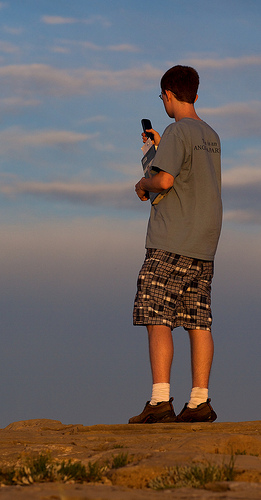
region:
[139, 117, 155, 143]
The phone held by the boy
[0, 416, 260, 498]
The stone ground the boy is standing on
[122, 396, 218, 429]
The boys brown shoes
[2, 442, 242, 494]
The grass on the stoney ground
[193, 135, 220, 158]
The writing on the back of the boy's shirt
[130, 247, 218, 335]
The boy's shorts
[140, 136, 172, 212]
The book under the boy's arm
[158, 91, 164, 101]
The portion of the boy's glasses shown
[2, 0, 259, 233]
Blue sky shown through the clouds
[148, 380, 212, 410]
The boy's white socks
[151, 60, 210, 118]
The teenager is wearing glasses.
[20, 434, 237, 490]
Tufts of grass coming out from in between the cracks.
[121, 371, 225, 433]
The socks are white.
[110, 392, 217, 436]
The shoes are brown.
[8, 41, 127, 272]
The sky is cloudy.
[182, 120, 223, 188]
Writing is on the back of the shirt.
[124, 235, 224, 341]
The shorts have black, white, and gray squares on them.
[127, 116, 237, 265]
The shirt is a bluish-gray color.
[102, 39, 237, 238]
The teenager is holding a phone.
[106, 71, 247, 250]
The teenager is holding a book under his arm.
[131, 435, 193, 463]
the dirt is brown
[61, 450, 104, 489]
the grass is green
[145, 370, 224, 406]
the socks are white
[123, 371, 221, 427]
the shoes are brown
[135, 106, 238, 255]
the shirt is gray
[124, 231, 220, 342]
the boy wears shorts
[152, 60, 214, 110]
the hair is short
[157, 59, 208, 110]
the hair is black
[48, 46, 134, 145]
the sky is blue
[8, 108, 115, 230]
the sky is cloudy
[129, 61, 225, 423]
young man using a cell phone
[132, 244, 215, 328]
shorts with a black and white checkered pattern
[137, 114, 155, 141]
a black rectangular cell phone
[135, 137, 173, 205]
book with a white paper held in it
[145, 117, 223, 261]
dark grey t-shirt with black lettering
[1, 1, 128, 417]
blue and grey cloudy sky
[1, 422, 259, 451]
flat rocky ground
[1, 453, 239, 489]
dry green grasses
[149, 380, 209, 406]
rolled white socks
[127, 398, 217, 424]
brown shoes with dark brown soles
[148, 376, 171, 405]
white long sock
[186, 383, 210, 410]
white long sock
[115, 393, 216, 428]
pair of brown shoes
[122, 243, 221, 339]
black and white shorts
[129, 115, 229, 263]
grey t shirt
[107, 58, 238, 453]
boy wearing a grey shirt looking at a phone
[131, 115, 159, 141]
black cell phone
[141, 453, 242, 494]
patch of green grass in tan dirt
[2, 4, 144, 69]
white clouds in blue sky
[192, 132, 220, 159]
black writing on a grey shirt